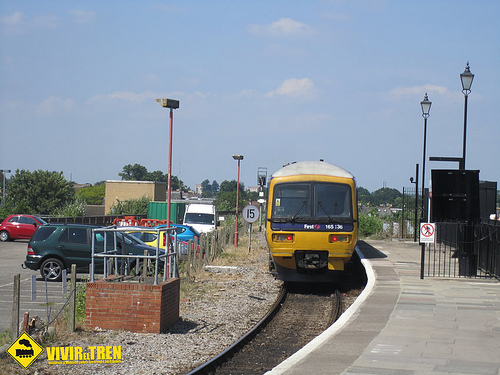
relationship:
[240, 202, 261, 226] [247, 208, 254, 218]
sign has 15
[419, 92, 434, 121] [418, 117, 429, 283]
light on pole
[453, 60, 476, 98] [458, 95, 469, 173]
light on pole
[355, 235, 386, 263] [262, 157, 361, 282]
shadow of train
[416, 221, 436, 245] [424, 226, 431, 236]
sign says no walking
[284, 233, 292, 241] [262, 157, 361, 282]
red light on train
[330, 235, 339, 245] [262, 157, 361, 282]
red light on train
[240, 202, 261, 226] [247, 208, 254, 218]
sign with 15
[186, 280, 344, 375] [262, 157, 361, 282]
tracks for train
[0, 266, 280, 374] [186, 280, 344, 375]
gravel beside tracks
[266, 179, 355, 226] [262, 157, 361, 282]
windshield on train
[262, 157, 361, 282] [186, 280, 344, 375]
train on tracks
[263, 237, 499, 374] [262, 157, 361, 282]
platform beside train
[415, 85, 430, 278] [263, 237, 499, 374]
lamppost on platform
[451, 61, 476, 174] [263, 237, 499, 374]
lamppost on platform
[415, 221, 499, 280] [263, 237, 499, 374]
fence on platform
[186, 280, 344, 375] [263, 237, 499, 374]
tracks beside platform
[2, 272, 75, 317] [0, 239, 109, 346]
white lines on parking lot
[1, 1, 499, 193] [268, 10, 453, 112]
sky with clouds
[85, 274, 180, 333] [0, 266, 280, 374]
structure on gravel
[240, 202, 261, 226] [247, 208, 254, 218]
sign says 15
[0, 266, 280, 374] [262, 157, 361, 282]
gravel by train